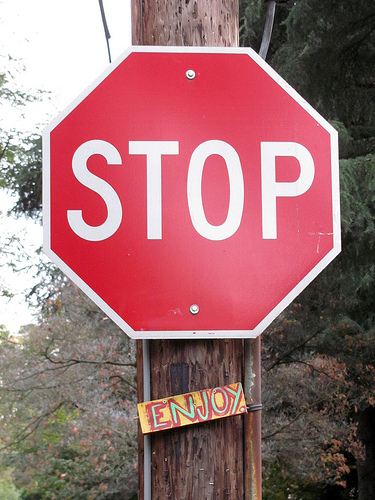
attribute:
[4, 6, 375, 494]
trees — thick, green, full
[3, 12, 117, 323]
sky — big, white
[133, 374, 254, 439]
enjoy sign — yellow, blue, red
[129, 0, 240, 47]
pole — wood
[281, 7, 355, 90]
leaves — green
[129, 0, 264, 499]
telephone pole — brown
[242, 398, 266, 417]
clips — small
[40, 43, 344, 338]
sign — stop sign, red, white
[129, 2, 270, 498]
pole — rusty, brown, tall, rust, thick, wooden, small